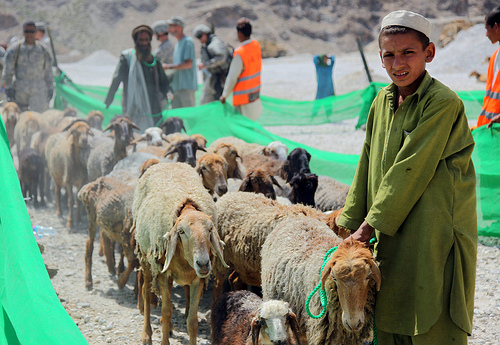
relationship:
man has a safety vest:
[219, 17, 264, 122] [221, 37, 263, 111]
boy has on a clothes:
[333, 8, 478, 345] [335, 70, 476, 345]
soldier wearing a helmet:
[193, 50, 219, 101] [204, 101, 229, 114]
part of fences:
[4, 145, 166, 174] [44, 67, 500, 234]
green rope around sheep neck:
[304, 236, 379, 345] [291, 245, 331, 288]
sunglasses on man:
[34, 50, 45, 60] [5, 20, 55, 102]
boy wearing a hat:
[371, 15, 436, 36] [376, 16, 477, 337]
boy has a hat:
[333, 8, 478, 345] [377, 8, 433, 40]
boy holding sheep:
[333, 8, 478, 345] [242, 239, 347, 345]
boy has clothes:
[333, 8, 478, 345] [356, 148, 453, 263]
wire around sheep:
[285, 244, 377, 298] [165, 151, 373, 325]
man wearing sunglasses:
[0, 20, 55, 114] [22, 27, 35, 34]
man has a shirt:
[168, 18, 198, 110] [174, 36, 197, 91]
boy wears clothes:
[333, 8, 478, 345] [339, 78, 487, 342]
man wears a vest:
[219, 20, 261, 120] [233, 38, 261, 104]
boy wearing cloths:
[333, 8, 478, 345] [369, 101, 479, 333]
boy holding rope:
[333, 8, 478, 345] [319, 250, 330, 323]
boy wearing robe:
[333, 8, 478, 345] [385, 94, 485, 341]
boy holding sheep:
[333, 8, 478, 345] [253, 212, 380, 336]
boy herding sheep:
[333, 8, 478, 345] [102, 156, 354, 336]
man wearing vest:
[219, 20, 261, 120] [232, 41, 260, 103]